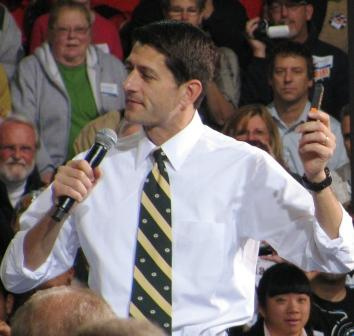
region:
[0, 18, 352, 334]
A man in a white shirt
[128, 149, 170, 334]
A black and yellow tie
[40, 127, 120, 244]
A cordless microphone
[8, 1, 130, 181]
a person in a green shirt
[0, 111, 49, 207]
a man in a white shirt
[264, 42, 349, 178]
A man in a blue shirt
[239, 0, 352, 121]
a man in a black shirt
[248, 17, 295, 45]
a handheld camcorder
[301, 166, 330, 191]
A black watch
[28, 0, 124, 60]
A person in a pink shirt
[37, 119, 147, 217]
a black microphone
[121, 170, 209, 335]
a striped tie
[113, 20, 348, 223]
a man wearing a ring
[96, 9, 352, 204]
a man wearing a watch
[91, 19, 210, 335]
a man wearing a striped tie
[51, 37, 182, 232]
a man holding a black microphone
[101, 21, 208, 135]
a man with brown hair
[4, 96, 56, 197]
a man with gray hair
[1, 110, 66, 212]
a man with facial hair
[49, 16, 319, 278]
a man wearing a white shirt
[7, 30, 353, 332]
man standing holding a microphone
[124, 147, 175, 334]
striped black and yellow tie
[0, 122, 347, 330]
white t-shirt of man in front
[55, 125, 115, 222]
black and gray microphone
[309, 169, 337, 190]
black watch on left arm of man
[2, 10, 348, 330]
people sitting behind man wearing white t-shirt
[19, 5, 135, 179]
fat woman wearing gray sweater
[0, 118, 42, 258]
man with white beard wearing black t-shirt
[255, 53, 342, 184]
man wearing light blue t-shirt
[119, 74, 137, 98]
profiled nose of man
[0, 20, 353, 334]
The man is holding a microphone.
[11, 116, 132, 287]
The microphone is wireless.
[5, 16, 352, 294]
The man is wearing a watch on his left wrist.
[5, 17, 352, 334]
The man is wearing a ring on his left hand.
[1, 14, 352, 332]
The man is wearing a white shirt.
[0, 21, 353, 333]
The man's shirt has long sleeves.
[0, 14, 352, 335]
The man's shirt sleeves are slightly rolled up.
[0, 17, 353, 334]
The man is wearing a tie.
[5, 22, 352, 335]
The man's tie has stripes and polks dots.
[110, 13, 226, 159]
The man has dark hair.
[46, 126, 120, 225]
silver microphone with black handle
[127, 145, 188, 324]
black and yellow men's tie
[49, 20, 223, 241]
man wearing tie holding microphone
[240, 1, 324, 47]
man using digital camcorder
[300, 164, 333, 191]
wrist watch with black band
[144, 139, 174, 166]
knot of necktie on white shirt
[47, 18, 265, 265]
man wearing white shirt and striped tie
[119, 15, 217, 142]
face of brown haired man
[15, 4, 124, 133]
woman wearing green shirt and grey hoodie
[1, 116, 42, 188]
man's face with white beard and mustache